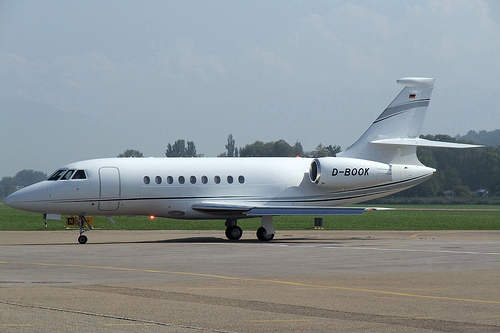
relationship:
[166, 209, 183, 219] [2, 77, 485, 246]
name on plane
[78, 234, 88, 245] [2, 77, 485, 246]
wheel of plane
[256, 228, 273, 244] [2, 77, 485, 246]
wheel of plane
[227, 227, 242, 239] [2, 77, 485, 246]
wheel of plane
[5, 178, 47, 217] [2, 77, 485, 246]
nose of plane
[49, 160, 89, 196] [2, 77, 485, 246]
cockpit of plane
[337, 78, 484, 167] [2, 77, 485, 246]
tail of plane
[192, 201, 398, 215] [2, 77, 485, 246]
wing of plane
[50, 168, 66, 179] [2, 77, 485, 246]
windshield to a plane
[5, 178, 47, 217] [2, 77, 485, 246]
nose of a plane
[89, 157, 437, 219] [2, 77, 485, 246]
body of plane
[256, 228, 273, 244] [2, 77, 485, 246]
wheel to a plane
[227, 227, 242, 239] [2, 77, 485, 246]
wheel to a plane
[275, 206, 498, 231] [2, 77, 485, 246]
grass behind plane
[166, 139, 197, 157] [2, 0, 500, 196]
tree in background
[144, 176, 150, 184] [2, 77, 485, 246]
window on plane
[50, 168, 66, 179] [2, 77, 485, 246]
windshield on a plane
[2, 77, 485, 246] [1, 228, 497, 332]
plane on ground